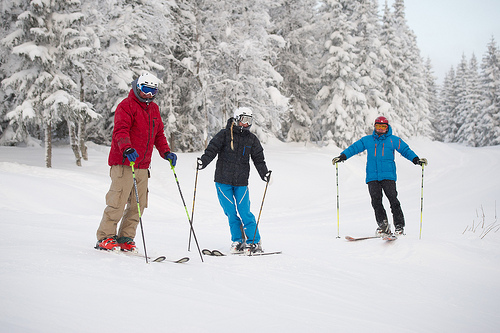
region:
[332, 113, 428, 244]
Person with blue winter coat on.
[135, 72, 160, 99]
White helmet on a mans head.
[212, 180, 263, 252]
bright blue snow pants on female.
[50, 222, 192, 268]
skis in the snow.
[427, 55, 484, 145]
Group of snowy trees.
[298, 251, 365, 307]
Lots of snow on the ground.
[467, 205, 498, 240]
Weeds coming through the snow.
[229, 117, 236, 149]
Blonde colored braid coming out of the helmet.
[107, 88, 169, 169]
Thick red winter coat on man.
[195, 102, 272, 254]
Blonde haired woman with white helmet on.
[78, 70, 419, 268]
these are three peope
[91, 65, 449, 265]
the people are snow skating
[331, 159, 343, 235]
this man is holding a pole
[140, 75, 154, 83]
the man has helmet on his head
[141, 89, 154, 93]
he is putting on goggles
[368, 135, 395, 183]
the jacket is blue in color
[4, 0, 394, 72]
the trees are filled with snow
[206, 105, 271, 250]
the man is bending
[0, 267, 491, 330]
snow are all over the place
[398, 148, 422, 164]
the mans hand is apart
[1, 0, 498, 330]
A winter photo of three skiers.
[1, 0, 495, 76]
A group of snow covered pine trees.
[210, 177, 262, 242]
The blue colored pants.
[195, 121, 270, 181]
The skier's black coat.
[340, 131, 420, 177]
The skier's blue coat.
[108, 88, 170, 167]
The skier's red coat.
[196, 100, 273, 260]
The middle skier leaning.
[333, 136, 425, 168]
The third skier's arms.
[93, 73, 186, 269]
The first skier's leaning forward.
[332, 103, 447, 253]
A person standing with skis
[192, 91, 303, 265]
A person in the middle with skis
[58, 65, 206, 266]
A person on the left with skis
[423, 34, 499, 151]
Pine trees covered with snow in the distance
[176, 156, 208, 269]
Two ski poles crossing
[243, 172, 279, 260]
A slanted ski pole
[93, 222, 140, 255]
Person wearing red ski shoes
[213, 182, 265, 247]
Blue ski pants with a white stripe on each side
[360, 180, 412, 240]
Black ski pants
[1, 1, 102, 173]
A pine tree covered in snow behind the skiers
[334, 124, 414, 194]
the jacket is blue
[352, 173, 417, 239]
the pants are black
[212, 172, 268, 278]
the pants are blue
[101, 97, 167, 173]
the jacket is red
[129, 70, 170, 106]
the helmet is white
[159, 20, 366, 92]
trees covered in snow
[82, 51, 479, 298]
three people on the snow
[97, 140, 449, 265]
people holding ski poles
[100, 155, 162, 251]
the pants are brown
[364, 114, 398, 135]
the helmet is red